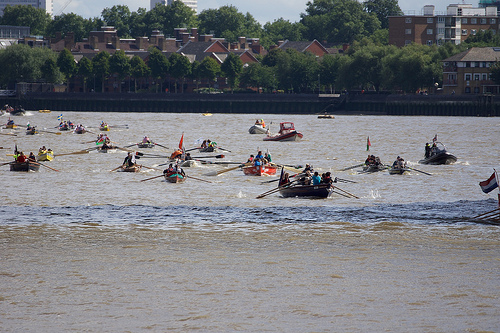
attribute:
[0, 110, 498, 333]
water — calm, brown, gray, a lake, grey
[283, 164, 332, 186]
people — rowing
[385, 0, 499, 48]
building — brick, apartments, multi level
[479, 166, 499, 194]
flag — red,white,blue, red, blue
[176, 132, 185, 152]
flag — orange, blue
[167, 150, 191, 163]
boat — small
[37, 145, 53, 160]
boat — yellow, small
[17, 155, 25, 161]
shirt — red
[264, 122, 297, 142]
boat — red, white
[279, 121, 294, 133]
cabin — red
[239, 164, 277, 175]
boat — red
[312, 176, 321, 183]
shirt — blue